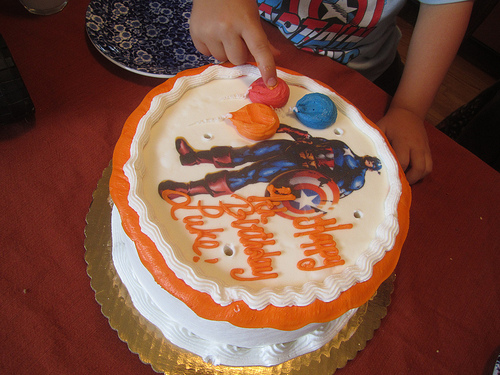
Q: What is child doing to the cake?
A: Touching icing.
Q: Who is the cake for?
A: Luke.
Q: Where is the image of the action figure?
A: On the cake.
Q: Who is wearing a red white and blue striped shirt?
A: Small boy.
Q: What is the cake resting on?
A: Gold paper tray.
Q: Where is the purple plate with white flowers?
A: Next to the boy.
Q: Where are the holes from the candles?
A: On top of the cake.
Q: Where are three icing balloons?
A: On top of the cake.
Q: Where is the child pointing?
A: To the red balloon.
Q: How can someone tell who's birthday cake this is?
A: Cake.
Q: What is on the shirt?
A: Captain America.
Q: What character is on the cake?
A: Captain America.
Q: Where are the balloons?
A: The cake.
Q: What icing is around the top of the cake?
A: Orange.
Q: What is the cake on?
A: Cardboard.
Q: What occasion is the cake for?
A: Birthday.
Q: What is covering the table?
A: Tablecloth.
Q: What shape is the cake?
A: Circle.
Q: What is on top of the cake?
A: Captain america.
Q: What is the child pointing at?
A: Balloon.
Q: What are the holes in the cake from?
A: Candles.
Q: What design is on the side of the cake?
A: Squiggles.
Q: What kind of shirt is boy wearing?
A: Captain america.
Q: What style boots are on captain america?
A: Red.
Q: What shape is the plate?
A: Circle.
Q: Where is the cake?
A: Table.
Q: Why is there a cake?
A: Birthday party.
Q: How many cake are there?
A: One.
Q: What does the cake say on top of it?
A: Happy Birthday Luke.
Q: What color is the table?
A: Red.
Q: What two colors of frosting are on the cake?
A: White, Orange.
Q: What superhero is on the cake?
A: Captain America.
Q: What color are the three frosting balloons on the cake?
A: Red, Orange, Blue.